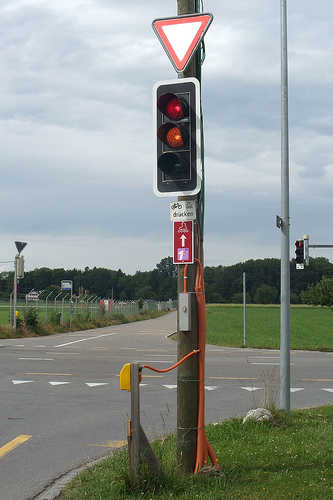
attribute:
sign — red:
[149, 12, 210, 75]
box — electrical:
[178, 290, 197, 337]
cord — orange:
[195, 263, 209, 464]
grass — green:
[56, 403, 332, 498]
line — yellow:
[0, 435, 37, 460]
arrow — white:
[10, 378, 38, 386]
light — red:
[159, 92, 189, 122]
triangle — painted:
[149, 12, 217, 76]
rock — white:
[241, 403, 272, 428]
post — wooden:
[175, 1, 206, 473]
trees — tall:
[0, 259, 331, 313]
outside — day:
[1, 1, 328, 498]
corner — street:
[74, 401, 309, 491]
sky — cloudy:
[2, 1, 331, 275]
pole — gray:
[272, 3, 293, 416]